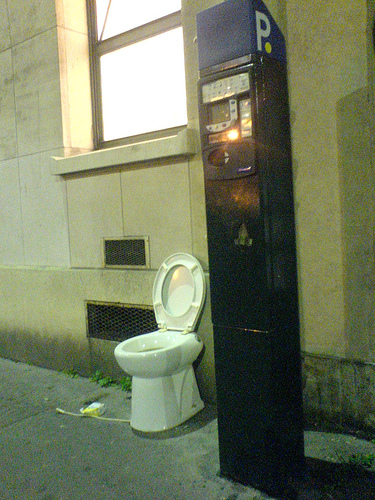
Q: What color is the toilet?
A: White.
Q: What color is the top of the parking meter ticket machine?
A: Blue.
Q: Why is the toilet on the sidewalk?
A: The toilet is broken.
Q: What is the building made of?
A: Cement.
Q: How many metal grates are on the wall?
A: Two.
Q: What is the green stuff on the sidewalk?
A: Weeds.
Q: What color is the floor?
A: Gray.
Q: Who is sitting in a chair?
A: No one.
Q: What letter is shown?
A: P.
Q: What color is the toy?
A: No toy.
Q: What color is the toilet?
A: White.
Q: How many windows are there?
A: One.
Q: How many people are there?
A: None.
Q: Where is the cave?
A: No cave.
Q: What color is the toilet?
A: White.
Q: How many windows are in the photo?
A: One.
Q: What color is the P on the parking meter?
A: White.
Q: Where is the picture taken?
A: A bathroom.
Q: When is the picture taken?
A: Daytime.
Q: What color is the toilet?
A: White.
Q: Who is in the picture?
A: No one.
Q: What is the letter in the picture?
A: P.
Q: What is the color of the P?
A: White.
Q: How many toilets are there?
A: One.